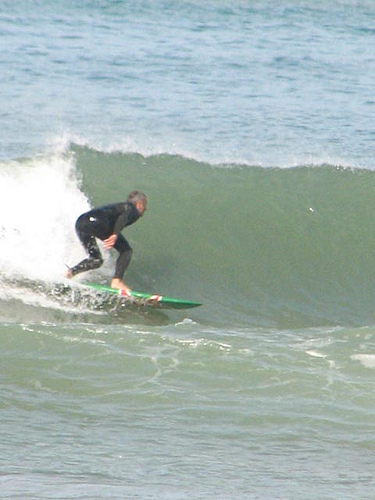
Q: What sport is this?
A: Surfing.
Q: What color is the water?
A: Green, blue.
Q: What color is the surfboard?
A: Green, red, white.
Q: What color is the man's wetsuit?
A: Black.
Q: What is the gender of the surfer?
A: Male.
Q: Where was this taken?
A: Ocean.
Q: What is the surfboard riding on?
A: Wave.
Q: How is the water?
A: Green and salty.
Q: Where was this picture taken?
A: The ocean.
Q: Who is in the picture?
A: A surfer.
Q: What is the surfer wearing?
A: A black wet suit.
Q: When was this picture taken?
A: Maybe afternoon.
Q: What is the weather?
A: Sunny.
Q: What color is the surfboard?
A: Green.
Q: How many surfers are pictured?
A: One.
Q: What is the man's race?
A: Caucasian.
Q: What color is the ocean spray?
A: White.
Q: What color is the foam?
A: White.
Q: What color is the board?
A: Green.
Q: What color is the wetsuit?
A: Black.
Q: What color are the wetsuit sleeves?
A: Black.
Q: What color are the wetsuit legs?
A: Black.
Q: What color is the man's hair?
A: Gray.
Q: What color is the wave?
A: Blue.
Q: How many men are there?
A: One.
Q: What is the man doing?
A: Surfing.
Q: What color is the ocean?
A: Green.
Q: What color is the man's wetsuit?
A: Black.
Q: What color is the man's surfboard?
A: Green.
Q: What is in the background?
A: The sea.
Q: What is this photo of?
A: A surfer riding the awesome waves.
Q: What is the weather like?
A: Sunny.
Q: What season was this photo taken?
A: Spring.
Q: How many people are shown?
A: One.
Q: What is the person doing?
A: Surfing.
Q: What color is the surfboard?
A: Green.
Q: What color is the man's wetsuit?
A: Black.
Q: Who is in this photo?
A: A surfer.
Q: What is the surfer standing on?
A: A surfboard.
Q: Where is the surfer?
A: On the ocean.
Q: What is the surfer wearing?
A: A wetsuit.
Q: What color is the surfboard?
A: Green.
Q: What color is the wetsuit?
A: Black.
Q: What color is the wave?
A: Blue and white.